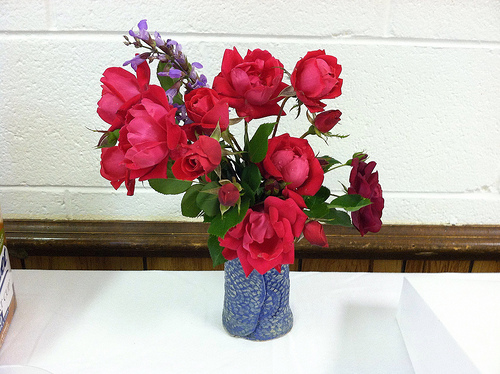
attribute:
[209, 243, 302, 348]
vase — blue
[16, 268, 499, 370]
table — white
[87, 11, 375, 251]
roses — red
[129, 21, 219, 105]
flowers — purple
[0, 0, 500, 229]
wall — white